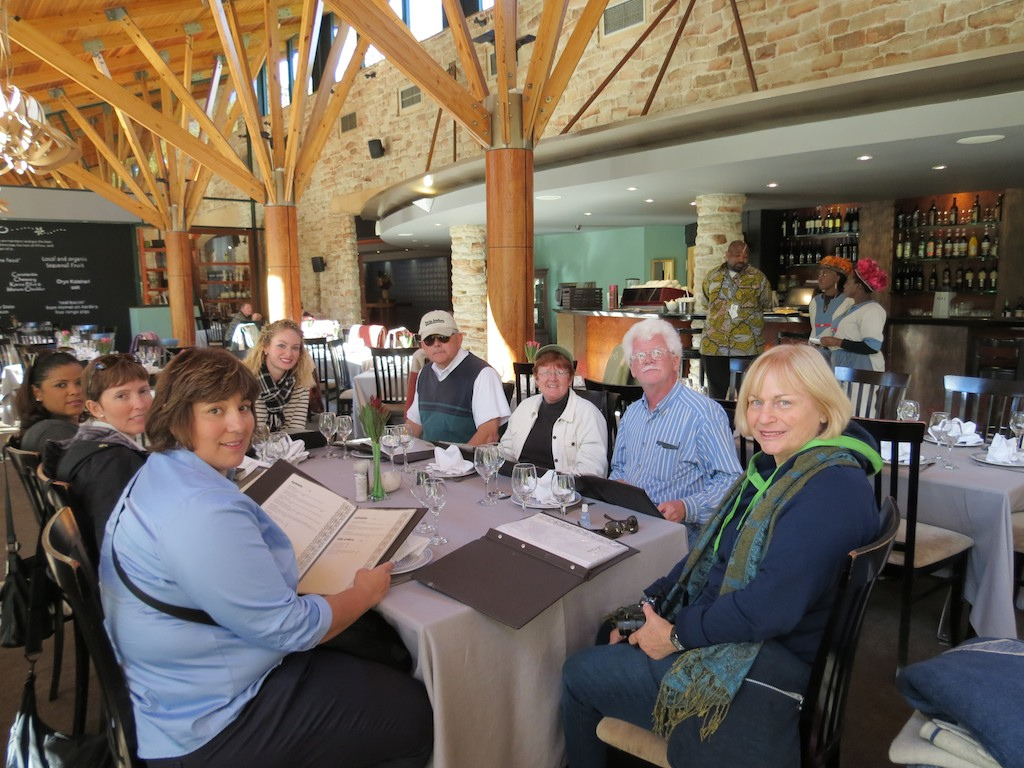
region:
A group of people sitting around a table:
[2, 307, 917, 764]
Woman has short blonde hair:
[718, 330, 861, 461]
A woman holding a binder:
[118, 330, 432, 659]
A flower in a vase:
[346, 383, 397, 504]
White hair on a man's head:
[607, 301, 690, 400]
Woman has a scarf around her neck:
[234, 307, 317, 443]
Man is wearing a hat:
[405, 299, 469, 372]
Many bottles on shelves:
[759, 177, 1007, 302]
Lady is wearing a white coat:
[479, 336, 612, 485]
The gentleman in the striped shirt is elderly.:
[600, 312, 747, 546]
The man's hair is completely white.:
[607, 309, 744, 545]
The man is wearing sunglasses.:
[395, 309, 512, 477]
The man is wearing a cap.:
[398, 306, 512, 472]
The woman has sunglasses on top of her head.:
[56, 344, 159, 554]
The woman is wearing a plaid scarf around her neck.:
[237, 316, 315, 450]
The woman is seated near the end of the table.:
[231, 313, 321, 451]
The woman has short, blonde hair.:
[723, 337, 857, 462]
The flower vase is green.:
[354, 386, 393, 505]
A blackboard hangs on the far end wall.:
[2, 217, 136, 363]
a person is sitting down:
[7, 338, 78, 460]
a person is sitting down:
[56, 341, 165, 598]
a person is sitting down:
[121, 344, 425, 762]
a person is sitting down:
[576, 353, 878, 765]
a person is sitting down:
[606, 310, 740, 554]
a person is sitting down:
[505, 351, 595, 487]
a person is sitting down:
[399, 316, 505, 454]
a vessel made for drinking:
[500, 456, 546, 548]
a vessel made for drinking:
[541, 455, 580, 548]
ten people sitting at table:
[30, 318, 874, 767]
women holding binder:
[103, 343, 433, 767]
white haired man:
[611, 317, 742, 532]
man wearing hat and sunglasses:
[400, 312, 509, 446]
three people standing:
[705, 239, 886, 361]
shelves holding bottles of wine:
[765, 195, 1000, 294]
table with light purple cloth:
[276, 437, 687, 767]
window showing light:
[251, 0, 504, 108]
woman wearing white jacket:
[497, 349, 605, 476]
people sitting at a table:
[16, 315, 873, 730]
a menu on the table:
[424, 514, 639, 626]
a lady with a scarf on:
[615, 373, 841, 750]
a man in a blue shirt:
[620, 320, 722, 505]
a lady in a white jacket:
[499, 345, 595, 459]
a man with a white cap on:
[400, 319, 493, 440]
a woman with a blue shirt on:
[135, 377, 354, 742]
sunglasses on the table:
[588, 514, 634, 531]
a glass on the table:
[477, 446, 498, 492]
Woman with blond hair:
[679, 338, 882, 734]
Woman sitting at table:
[638, 334, 896, 731]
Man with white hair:
[601, 310, 737, 530]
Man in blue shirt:
[600, 310, 740, 520]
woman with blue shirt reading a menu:
[88, 339, 439, 766]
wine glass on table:
[508, 456, 535, 529]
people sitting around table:
[0, 309, 907, 766]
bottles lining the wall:
[748, 187, 1006, 321]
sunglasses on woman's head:
[81, 347, 149, 404]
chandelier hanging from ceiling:
[0, 0, 77, 181]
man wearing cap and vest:
[392, 309, 514, 450]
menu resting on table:
[408, 509, 643, 633]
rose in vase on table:
[351, 391, 394, 502]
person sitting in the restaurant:
[89, 348, 438, 766]